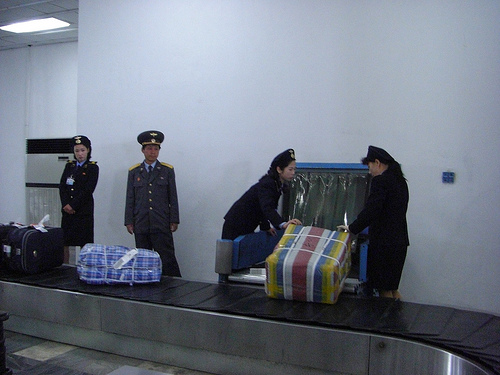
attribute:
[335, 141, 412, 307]
lady — standing, working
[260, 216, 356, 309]
luggage — multicolored, many colors, checked, striped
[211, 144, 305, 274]
lady — standing, working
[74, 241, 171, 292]
bag — blue, checked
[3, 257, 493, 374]
conveyor belt — black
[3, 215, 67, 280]
bag — black, checked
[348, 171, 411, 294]
uniform — black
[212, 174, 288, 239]
uniform — black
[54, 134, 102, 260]
lady — standing, working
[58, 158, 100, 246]
uniform — black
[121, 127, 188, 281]
man — standing, working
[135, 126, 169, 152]
hat — grey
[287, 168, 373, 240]
door — plastic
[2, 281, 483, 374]
side — silver, metal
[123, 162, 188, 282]
uniform — black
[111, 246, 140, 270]
tag — white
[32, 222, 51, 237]
tag — white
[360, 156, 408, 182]
hair — black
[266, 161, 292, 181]
hair — black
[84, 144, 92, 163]
hair — black